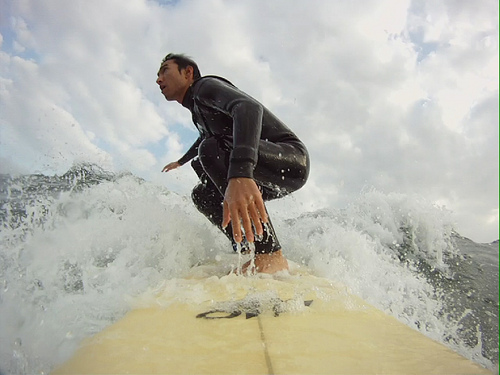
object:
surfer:
[148, 45, 320, 287]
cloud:
[338, 32, 458, 174]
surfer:
[148, 46, 310, 276]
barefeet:
[205, 249, 296, 291]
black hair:
[159, 53, 201, 78]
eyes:
[160, 64, 167, 75]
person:
[137, 45, 332, 280]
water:
[10, 152, 490, 364]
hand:
[213, 179, 278, 251]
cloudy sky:
[4, 2, 500, 181]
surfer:
[153, 53, 310, 295]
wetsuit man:
[150, 52, 310, 278]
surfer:
[157, 47, 321, 371]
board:
[44, 273, 499, 374]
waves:
[1, 159, 498, 374]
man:
[123, 32, 342, 252]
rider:
[155, 51, 310, 276]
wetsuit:
[178, 75, 308, 253]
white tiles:
[52, 181, 148, 298]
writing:
[190, 288, 301, 328]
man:
[145, 42, 323, 284]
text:
[190, 289, 317, 323]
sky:
[10, 16, 479, 176]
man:
[153, 48, 317, 278]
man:
[139, 55, 319, 282]